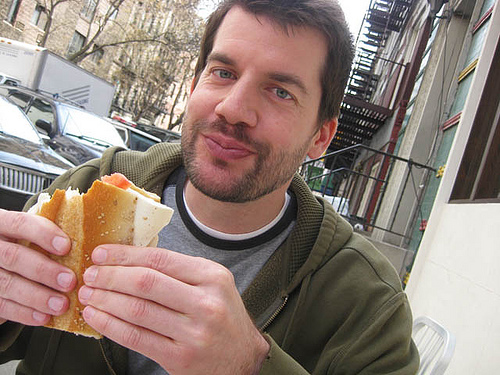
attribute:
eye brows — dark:
[205, 49, 310, 98]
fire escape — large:
[322, 0, 419, 175]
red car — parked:
[107, 113, 139, 126]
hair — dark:
[193, 0, 359, 128]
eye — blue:
[271, 85, 296, 104]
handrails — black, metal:
[302, 143, 444, 215]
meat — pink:
[102, 171, 132, 190]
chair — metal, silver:
[401, 298, 454, 375]